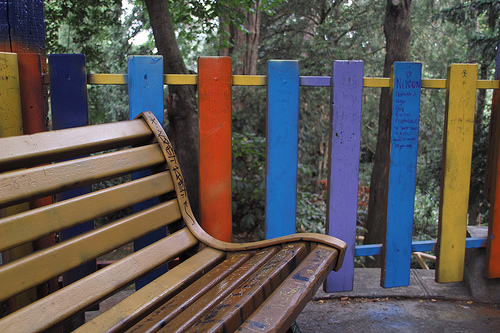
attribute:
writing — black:
[391, 75, 422, 155]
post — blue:
[126, 44, 180, 134]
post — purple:
[325, 59, 353, 291]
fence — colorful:
[47, 55, 499, 282]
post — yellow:
[436, 59, 478, 290]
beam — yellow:
[43, 68, 498, 98]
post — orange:
[193, 53, 233, 241]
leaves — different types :
[40, 3, 128, 65]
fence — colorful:
[57, 50, 489, 309]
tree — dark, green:
[432, 13, 487, 65]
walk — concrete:
[280, 266, 499, 331]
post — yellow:
[438, 51, 476, 306]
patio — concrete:
[296, 267, 498, 332]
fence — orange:
[225, 71, 498, 216]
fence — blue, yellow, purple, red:
[3, 51, 498, 291]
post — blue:
[265, 59, 295, 236]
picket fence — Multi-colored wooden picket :
[5, 47, 497, 301]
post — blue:
[375, 56, 420, 290]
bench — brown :
[19, 112, 398, 330]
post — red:
[187, 45, 253, 256]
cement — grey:
[345, 245, 495, 330]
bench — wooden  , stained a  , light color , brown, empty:
[0, 109, 347, 330]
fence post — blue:
[380, 58, 426, 289]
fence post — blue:
[320, 60, 365, 296]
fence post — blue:
[259, 57, 302, 242]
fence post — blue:
[119, 52, 168, 131]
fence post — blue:
[48, 47, 85, 134]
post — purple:
[320, 60, 363, 297]